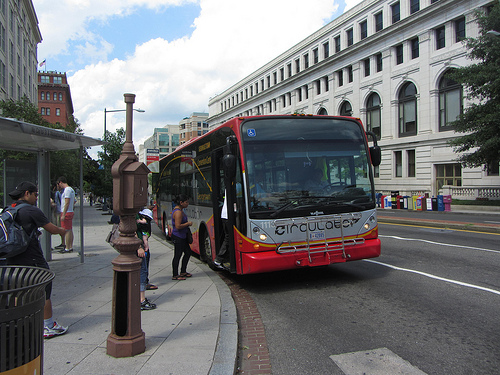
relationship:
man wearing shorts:
[52, 175, 80, 255] [58, 210, 76, 230]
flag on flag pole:
[37, 54, 47, 69] [43, 56, 48, 72]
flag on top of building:
[37, 54, 47, 69] [34, 68, 75, 131]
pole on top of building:
[44, 58, 49, 74] [34, 68, 75, 131]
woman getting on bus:
[166, 193, 195, 285] [144, 111, 386, 278]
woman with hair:
[166, 193, 195, 285] [171, 191, 186, 206]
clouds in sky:
[83, 17, 262, 103] [35, 3, 350, 150]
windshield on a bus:
[237, 115, 376, 214] [144, 111, 386, 278]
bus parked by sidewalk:
[144, 111, 386, 278] [39, 196, 239, 372]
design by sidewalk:
[232, 277, 274, 374] [39, 196, 239, 372]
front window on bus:
[239, 117, 374, 217] [144, 111, 386, 278]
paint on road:
[370, 231, 498, 294] [248, 218, 497, 373]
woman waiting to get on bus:
[166, 193, 195, 285] [144, 111, 386, 278]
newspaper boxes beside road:
[379, 187, 456, 211] [248, 218, 497, 373]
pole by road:
[101, 90, 154, 359] [248, 218, 497, 373]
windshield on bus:
[237, 115, 376, 214] [144, 111, 386, 278]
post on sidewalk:
[77, 145, 86, 259] [39, 196, 239, 372]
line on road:
[364, 229, 499, 295] [248, 218, 497, 373]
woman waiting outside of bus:
[166, 193, 195, 285] [144, 111, 386, 278]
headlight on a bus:
[258, 230, 267, 243] [144, 111, 386, 278]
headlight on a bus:
[362, 219, 373, 232] [144, 111, 386, 278]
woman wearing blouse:
[166, 193, 195, 285] [168, 207, 194, 240]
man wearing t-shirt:
[52, 175, 80, 255] [59, 184, 76, 216]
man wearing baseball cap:
[1, 184, 68, 340] [10, 178, 38, 203]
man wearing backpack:
[1, 184, 68, 340] [0, 200, 37, 257]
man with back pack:
[1, 184, 68, 340] [0, 200, 35, 257]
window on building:
[361, 90, 386, 143] [205, 1, 499, 208]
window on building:
[390, 75, 419, 141] [205, 1, 499, 208]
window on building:
[430, 60, 472, 136] [205, 1, 499, 208]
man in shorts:
[52, 175, 80, 255] [58, 210, 76, 230]